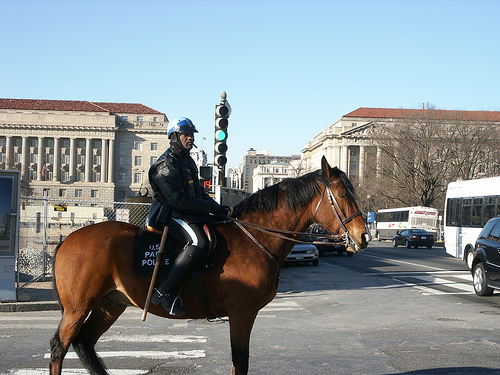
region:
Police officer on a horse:
[28, 110, 378, 373]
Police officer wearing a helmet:
[142, 107, 227, 330]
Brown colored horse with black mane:
[35, 150, 425, 373]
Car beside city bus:
[356, 197, 447, 261]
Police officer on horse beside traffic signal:
[33, 84, 383, 373]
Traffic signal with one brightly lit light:
[195, 76, 257, 216]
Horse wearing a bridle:
[228, 154, 385, 365]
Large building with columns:
[0, 91, 147, 205]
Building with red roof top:
[297, 99, 499, 201]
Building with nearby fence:
[5, 91, 149, 224]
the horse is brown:
[31, 141, 373, 354]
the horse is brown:
[4, 85, 278, 306]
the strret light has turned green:
[211, 101, 236, 171]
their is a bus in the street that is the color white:
[446, 181, 498, 261]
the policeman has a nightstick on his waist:
[135, 223, 177, 325]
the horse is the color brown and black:
[69, 171, 339, 327]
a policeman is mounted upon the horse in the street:
[148, 112, 217, 312]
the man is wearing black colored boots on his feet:
[146, 277, 191, 317]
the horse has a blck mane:
[237, 174, 316, 212]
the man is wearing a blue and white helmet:
[156, 115, 200, 136]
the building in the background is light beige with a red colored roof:
[0, 98, 155, 238]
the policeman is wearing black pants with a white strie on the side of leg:
[169, 212, 211, 249]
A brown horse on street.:
[36, 160, 406, 372]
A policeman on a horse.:
[142, 115, 222, 311]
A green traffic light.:
[210, 124, 232, 144]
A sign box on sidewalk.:
[1, 160, 23, 302]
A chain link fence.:
[21, 192, 52, 279]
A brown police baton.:
[140, 220, 165, 321]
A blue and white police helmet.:
[165, 113, 197, 139]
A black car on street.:
[389, 227, 439, 248]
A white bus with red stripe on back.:
[370, 202, 438, 247]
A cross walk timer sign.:
[195, 175, 220, 194]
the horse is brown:
[129, 160, 319, 351]